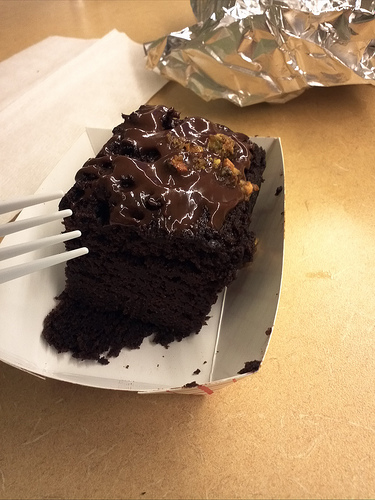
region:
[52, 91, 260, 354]
piece of chocolate cake in tray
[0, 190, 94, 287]
white plastic fork used for eating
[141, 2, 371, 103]
crumpled piece of tinfoil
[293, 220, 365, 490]
beige counter top where cake is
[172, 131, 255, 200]
nuts on top of cake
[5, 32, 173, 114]
white napkin on side of food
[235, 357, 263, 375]
piece of cake on corner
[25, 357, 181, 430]
paper tray cake is in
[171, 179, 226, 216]
chocolate icing on the cake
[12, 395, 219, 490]
shadow on the table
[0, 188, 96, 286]
the tines of a white plastic fork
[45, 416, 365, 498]
the tan surface of the table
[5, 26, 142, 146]
white napkin next to the tray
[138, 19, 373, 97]
alumnum foil next to the tray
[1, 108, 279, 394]
white tray with a brownie inside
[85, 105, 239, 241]
shiny topping on the brownie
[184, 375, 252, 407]
red stripes on the side of the tray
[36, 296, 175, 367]
extra base from another brown piece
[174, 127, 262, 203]
nuts in the brownie topping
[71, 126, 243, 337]
a chocolate brownie in a white tray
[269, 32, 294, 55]
part of a foil paper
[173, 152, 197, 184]
top layer of a cake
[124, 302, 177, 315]
bottom part of a cake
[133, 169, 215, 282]
piece of a black forest cake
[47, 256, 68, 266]
front part of a fork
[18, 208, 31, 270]
section of a fork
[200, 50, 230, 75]
shiny foil paper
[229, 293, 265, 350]
edge of a white small box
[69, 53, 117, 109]
section of a white piece of paper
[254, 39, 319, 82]
outer part of a foil paper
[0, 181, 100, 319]
tines of a plastic fork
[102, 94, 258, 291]
gooey chocolate frosting on brownie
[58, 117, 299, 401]
brownie in a cardboard basket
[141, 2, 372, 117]
crumpled wad of aluminum foil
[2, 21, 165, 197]
white unused napkin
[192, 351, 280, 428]
brownie crumbs on the edge of the basket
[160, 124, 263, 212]
nuts on top of a brownie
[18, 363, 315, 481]
basket on a tan counter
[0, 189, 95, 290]
white plastic fork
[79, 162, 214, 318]
chocolate thick brownie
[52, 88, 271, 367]
cake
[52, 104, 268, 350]
chocolate cake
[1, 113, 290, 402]
a piece of chocolate cake in a white paper dish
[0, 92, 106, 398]
a white plastic fork is near the cake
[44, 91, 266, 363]
the cake has chocolate frosting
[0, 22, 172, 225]
a white paper towel on the table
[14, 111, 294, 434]
the dish is made of paper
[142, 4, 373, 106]
a piece of aluminum foil is crumpled on the table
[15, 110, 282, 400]
a dish of cake on a table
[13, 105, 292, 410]
a dessert dish